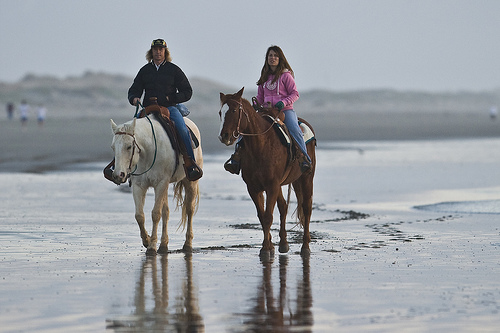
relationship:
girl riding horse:
[252, 37, 316, 172] [209, 88, 326, 259]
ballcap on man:
[148, 37, 169, 51] [137, 30, 184, 90]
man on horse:
[137, 30, 184, 90] [96, 113, 190, 225]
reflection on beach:
[105, 255, 204, 332] [0, 117, 499, 330]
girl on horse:
[223, 46, 312, 176] [212, 85, 319, 260]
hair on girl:
[258, 64, 269, 86] [223, 46, 312, 176]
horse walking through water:
[208, 94, 269, 186] [400, 187, 486, 220]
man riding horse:
[104, 38, 202, 184] [217, 85, 317, 251]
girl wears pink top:
[223, 46, 312, 176] [254, 71, 298, 109]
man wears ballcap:
[104, 38, 202, 184] [149, 38, 167, 48]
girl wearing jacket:
[223, 46, 312, 176] [256, 65, 298, 102]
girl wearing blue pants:
[223, 46, 312, 176] [285, 104, 309, 156]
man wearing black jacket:
[104, 38, 202, 184] [126, 59, 192, 109]